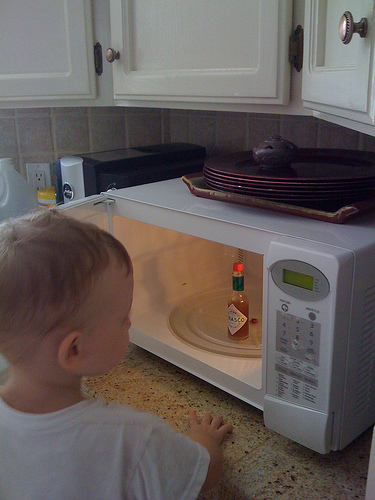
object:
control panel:
[261, 242, 336, 417]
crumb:
[250, 318, 258, 324]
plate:
[169, 281, 263, 360]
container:
[37, 187, 57, 210]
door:
[0, 192, 114, 374]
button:
[263, 392, 331, 455]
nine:
[309, 339, 314, 345]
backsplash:
[2, 107, 374, 214]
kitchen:
[2, 0, 373, 495]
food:
[182, 282, 186, 286]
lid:
[233, 262, 243, 272]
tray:
[181, 174, 372, 228]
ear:
[58, 329, 81, 371]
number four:
[283, 321, 287, 327]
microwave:
[0, 177, 375, 455]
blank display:
[283, 269, 313, 291]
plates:
[201, 143, 373, 205]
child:
[1, 207, 236, 498]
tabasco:
[227, 261, 250, 341]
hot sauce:
[228, 301, 250, 339]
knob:
[338, 9, 368, 46]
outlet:
[26, 161, 51, 192]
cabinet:
[0, 0, 297, 110]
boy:
[0, 208, 234, 499]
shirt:
[0, 395, 209, 499]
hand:
[184, 409, 232, 441]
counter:
[114, 354, 372, 498]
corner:
[8, 114, 243, 215]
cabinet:
[301, 0, 375, 130]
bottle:
[227, 261, 249, 341]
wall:
[2, 111, 373, 213]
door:
[302, 0, 375, 116]